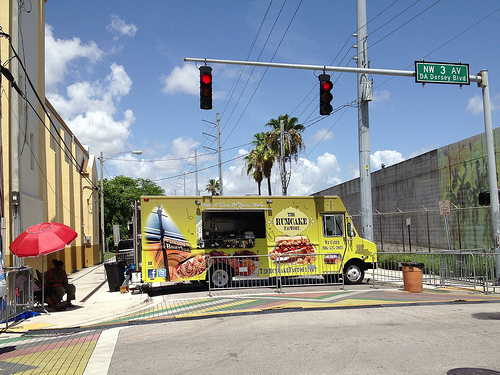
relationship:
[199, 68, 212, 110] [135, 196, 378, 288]
signal over truck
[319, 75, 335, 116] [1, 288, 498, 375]
signal over road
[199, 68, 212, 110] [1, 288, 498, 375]
signal over road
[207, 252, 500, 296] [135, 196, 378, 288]
guardrail beside truck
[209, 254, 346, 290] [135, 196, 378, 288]
guardrail beside truck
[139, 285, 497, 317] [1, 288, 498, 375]
crosswalk on road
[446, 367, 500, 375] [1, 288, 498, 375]
manhole on road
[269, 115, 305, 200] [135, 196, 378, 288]
tree behind truck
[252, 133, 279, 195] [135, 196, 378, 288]
tree behind truck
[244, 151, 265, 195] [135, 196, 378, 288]
tree behind truck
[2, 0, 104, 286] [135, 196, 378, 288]
building behind truck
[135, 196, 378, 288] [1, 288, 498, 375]
truck in road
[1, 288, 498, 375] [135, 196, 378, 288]
road underneath truck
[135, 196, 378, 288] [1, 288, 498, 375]
truck on road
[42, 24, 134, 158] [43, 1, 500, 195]
clouds in sky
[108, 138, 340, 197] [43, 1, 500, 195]
clouds in sky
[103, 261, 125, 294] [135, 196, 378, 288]
can behind truck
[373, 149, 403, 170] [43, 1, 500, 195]
clouds in sky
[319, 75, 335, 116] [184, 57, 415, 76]
signal on pole